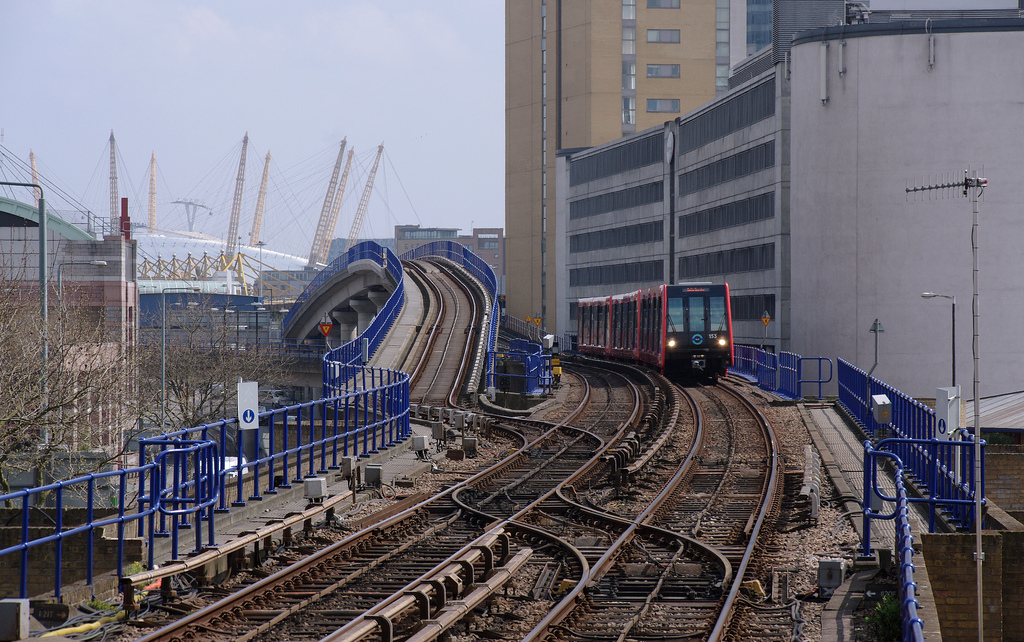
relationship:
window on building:
[586, 186, 610, 215] [531, 14, 1013, 472]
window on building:
[642, 53, 686, 84] [493, 9, 723, 359]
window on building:
[644, 93, 684, 124] [493, 9, 723, 359]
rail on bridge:
[385, 310, 470, 395] [281, 232, 500, 380]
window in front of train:
[707, 282, 733, 343] [655, 275, 733, 371]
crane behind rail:
[325, 150, 367, 252] [401, 259, 477, 400]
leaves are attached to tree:
[216, 340, 271, 367] [211, 336, 259, 406]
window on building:
[712, 236, 779, 295] [459, 63, 956, 480]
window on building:
[679, 242, 775, 278] [498, 95, 1008, 452]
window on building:
[679, 242, 775, 278] [531, 33, 996, 448]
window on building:
[633, 258, 651, 280] [555, 1, 1022, 397]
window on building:
[618, 255, 642, 281] [555, 1, 1022, 397]